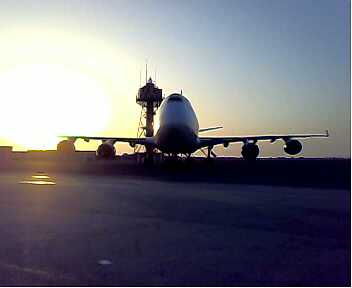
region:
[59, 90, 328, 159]
An aircraft ready for take off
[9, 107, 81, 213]
The brightened right side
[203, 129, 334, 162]
The plane double engine right wing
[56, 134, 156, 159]
The plane double engine left wing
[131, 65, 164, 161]
The airport tower behind the plane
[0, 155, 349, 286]
The darkened airport grounds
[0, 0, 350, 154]
A bright blue sky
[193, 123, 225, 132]
The partially blocked plane tail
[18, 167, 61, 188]
The brightly glowing ground.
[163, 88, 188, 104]
The top pilots compartment window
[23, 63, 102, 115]
A sitting sun light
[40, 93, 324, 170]
A landing white plane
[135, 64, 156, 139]
A big tall transfommer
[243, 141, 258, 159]
A small plane wheel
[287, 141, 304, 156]
A small plane wheel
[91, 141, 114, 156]
A small plane wheel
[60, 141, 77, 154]
A small plane wheel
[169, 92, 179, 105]
A small plane window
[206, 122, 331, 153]
A big plane wing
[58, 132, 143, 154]
A big plane wing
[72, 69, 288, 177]
white plane on tarmac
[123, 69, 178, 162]
control tower behind plane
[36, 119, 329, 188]
plane has four engines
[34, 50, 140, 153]
sun shines next to plane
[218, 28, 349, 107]
sky is blue and hazy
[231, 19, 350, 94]
no clouds in sky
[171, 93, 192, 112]
window at top of plane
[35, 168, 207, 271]
tarmac is dark grey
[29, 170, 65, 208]
sun reflects off left side of tarmac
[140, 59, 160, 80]
antennae on control tower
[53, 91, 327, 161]
this is a plane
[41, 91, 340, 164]
the plane is standing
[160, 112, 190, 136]
this is the head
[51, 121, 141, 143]
this is the wing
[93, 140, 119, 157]
this s the propeller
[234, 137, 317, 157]
the propellers are two in number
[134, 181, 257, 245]
this is a run way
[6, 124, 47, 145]
the sun is setting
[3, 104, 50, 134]
the rays are bright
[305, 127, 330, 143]
the wing is sharp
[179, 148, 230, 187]
plane on the tarmac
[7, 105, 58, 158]
sun is not up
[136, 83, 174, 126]
plane tower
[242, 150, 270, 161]
four engines on the plane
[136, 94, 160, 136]
tower is on a pole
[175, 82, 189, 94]
tail of the plane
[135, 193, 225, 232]
ground looks dark grey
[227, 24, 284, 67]
sky has a grey color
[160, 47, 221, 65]
sky has a blue next to the grey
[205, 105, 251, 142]
orange next to the blue in the sky